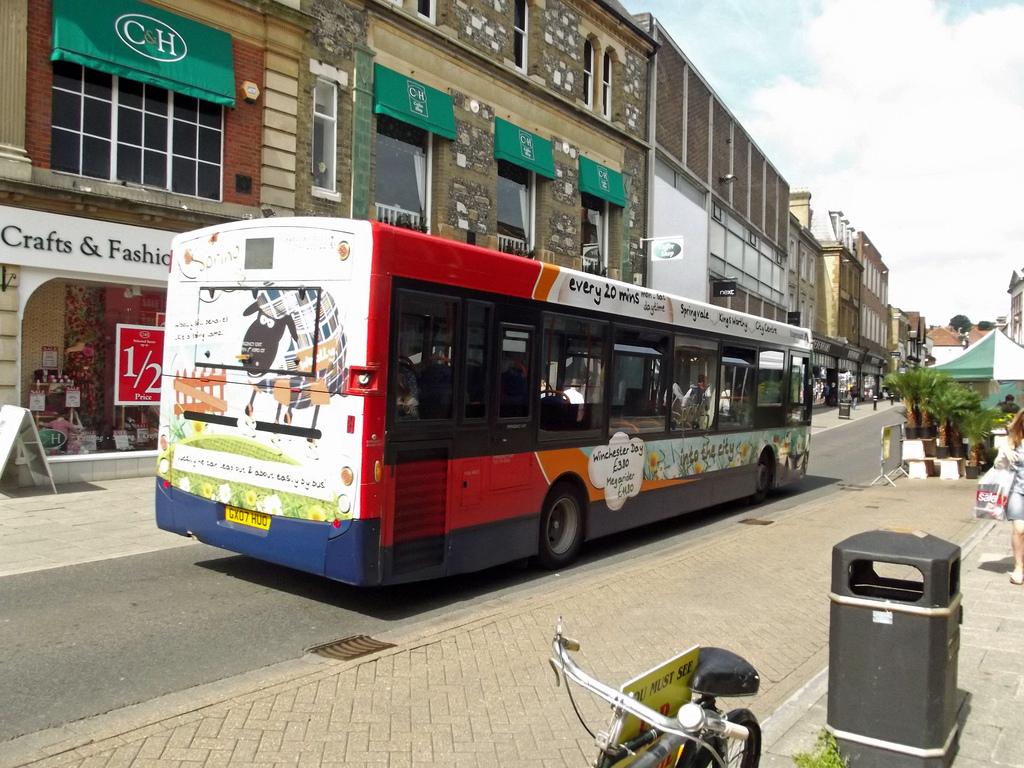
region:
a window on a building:
[372, 114, 437, 222]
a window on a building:
[504, 162, 530, 249]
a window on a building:
[574, 187, 620, 286]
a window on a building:
[609, 45, 635, 162]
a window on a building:
[580, 25, 593, 127]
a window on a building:
[502, 1, 550, 85]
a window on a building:
[413, 10, 434, 23]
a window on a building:
[19, 260, 169, 460]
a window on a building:
[62, 44, 116, 190]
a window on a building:
[119, 54, 174, 203]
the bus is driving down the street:
[76, 216, 864, 631]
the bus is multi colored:
[106, 226, 850, 577]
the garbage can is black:
[779, 500, 963, 734]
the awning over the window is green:
[10, 0, 254, 130]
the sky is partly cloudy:
[678, 0, 995, 197]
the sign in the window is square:
[92, 305, 168, 416]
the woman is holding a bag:
[974, 389, 1016, 596]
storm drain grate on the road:
[307, 628, 391, 666]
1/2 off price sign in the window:
[118, 322, 164, 406]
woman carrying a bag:
[977, 413, 1022, 528]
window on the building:
[311, 75, 341, 202]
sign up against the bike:
[623, 661, 703, 706]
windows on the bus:
[396, 300, 545, 452]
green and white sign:
[637, 236, 683, 263]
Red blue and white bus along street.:
[133, 210, 826, 591]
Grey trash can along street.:
[820, 523, 977, 764]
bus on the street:
[230, 326, 825, 489]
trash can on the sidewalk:
[814, 515, 964, 746]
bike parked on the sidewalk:
[523, 614, 765, 764]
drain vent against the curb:
[309, 621, 401, 683]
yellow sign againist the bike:
[633, 667, 685, 700]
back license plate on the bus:
[197, 487, 289, 541]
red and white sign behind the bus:
[106, 318, 164, 391]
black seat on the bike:
[681, 638, 761, 692]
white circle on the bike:
[677, 700, 704, 732]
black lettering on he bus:
[556, 271, 806, 345]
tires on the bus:
[524, 439, 803, 579]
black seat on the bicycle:
[688, 639, 753, 694]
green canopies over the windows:
[51, 7, 640, 192]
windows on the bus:
[378, 278, 815, 446]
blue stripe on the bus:
[149, 471, 794, 599]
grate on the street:
[293, 616, 398, 683]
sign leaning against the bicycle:
[593, 635, 702, 750]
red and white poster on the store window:
[106, 319, 164, 405]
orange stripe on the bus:
[531, 271, 671, 509]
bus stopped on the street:
[170, 208, 838, 542]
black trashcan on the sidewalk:
[828, 531, 953, 766]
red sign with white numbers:
[117, 322, 162, 400]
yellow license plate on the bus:
[220, 499, 274, 538]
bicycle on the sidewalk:
[543, 606, 760, 766]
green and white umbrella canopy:
[923, 323, 1022, 396]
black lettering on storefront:
[3, 205, 166, 288]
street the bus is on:
[0, 385, 920, 699]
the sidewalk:
[309, 715, 439, 750]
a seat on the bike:
[673, 644, 766, 701]